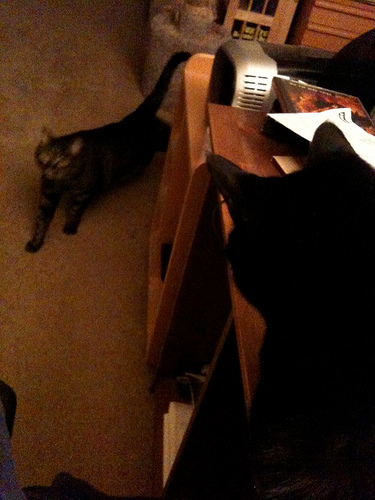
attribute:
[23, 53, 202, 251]
cat — inside, walking, grey, black, on floor, tabby, tabby cat, stretching, looking, curious, looking up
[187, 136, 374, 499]
cat — inside, black, looking down, perched, sitting, looking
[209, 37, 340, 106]
printer — on top, ink jet, silver, black, grey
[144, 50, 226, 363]
stand — small, brown, wood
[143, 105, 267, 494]
furniture — for office, brown, wooden, big, wood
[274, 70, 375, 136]
dvd — multicolored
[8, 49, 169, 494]
carpet — light brown, tan, on floor, dark gold, beige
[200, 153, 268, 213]
ears — up, oval, large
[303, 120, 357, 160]
ears — up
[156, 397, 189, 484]
documents — white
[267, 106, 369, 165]
letter — white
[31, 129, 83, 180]
face — brown, tan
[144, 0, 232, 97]
post — scratching post, for cats